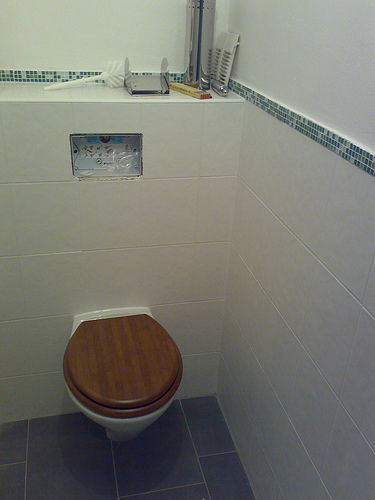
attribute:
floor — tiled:
[3, 390, 259, 500]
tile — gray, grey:
[175, 392, 242, 461]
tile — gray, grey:
[193, 444, 258, 500]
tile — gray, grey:
[103, 393, 211, 497]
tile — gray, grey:
[22, 412, 126, 499]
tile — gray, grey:
[1, 417, 32, 468]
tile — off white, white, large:
[195, 95, 250, 179]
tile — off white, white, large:
[191, 172, 243, 247]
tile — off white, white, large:
[136, 99, 207, 183]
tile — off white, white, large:
[129, 173, 203, 251]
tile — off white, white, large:
[182, 237, 235, 304]